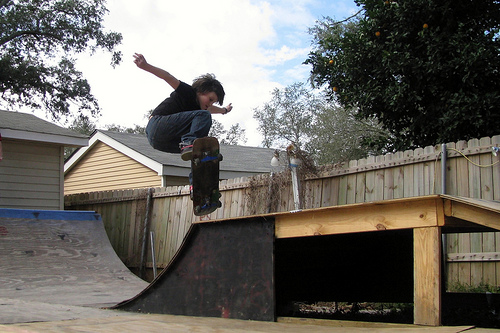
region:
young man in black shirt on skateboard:
[133, 53, 233, 215]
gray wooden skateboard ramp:
[0, 208, 277, 322]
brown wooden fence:
[63, 133, 499, 308]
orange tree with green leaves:
[301, 0, 498, 156]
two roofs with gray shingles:
[0, 110, 318, 173]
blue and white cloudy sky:
[0, 0, 497, 155]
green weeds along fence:
[298, 277, 498, 322]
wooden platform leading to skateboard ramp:
[272, 193, 499, 325]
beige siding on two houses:
[1, 138, 227, 210]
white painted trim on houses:
[0, 128, 268, 187]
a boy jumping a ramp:
[123, 43, 240, 217]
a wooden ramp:
[114, 204, 491, 321]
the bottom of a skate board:
[188, 136, 225, 217]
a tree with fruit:
[315, 3, 495, 138]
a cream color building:
[1, 105, 91, 202]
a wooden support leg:
[411, 227, 434, 325]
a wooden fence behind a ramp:
[304, 158, 496, 303]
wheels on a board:
[189, 152, 226, 167]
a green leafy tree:
[0, 5, 120, 112]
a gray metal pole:
[440, 143, 450, 185]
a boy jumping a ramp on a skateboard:
[76, 66, 287, 318]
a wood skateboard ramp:
[2, 192, 445, 317]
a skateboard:
[184, 121, 230, 223]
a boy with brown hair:
[188, 76, 236, 111]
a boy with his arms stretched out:
[126, 53, 258, 123]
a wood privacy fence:
[248, 141, 473, 227]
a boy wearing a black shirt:
[158, 69, 208, 132]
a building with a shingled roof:
[220, 136, 269, 193]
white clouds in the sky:
[224, 15, 310, 67]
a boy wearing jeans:
[160, 74, 212, 154]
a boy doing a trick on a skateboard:
[131, 50, 232, 217]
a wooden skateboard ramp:
[0, 190, 495, 324]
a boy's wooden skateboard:
[189, 137, 224, 215]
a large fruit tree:
[304, 1, 497, 148]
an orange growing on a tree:
[328, 57, 335, 65]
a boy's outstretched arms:
[131, 50, 237, 115]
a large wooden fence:
[64, 136, 498, 291]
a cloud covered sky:
[2, 1, 367, 146]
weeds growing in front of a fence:
[446, 280, 498, 295]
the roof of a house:
[1, 108, 92, 146]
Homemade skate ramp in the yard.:
[0, 191, 204, 318]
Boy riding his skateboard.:
[105, 42, 251, 225]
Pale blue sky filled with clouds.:
[181, 0, 325, 59]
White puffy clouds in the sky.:
[133, 20, 289, 72]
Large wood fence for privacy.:
[330, 138, 494, 201]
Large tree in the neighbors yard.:
[315, 10, 483, 136]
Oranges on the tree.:
[320, 14, 440, 76]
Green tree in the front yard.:
[6, 8, 114, 115]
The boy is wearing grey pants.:
[138, 106, 220, 156]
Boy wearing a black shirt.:
[145, 80, 223, 120]